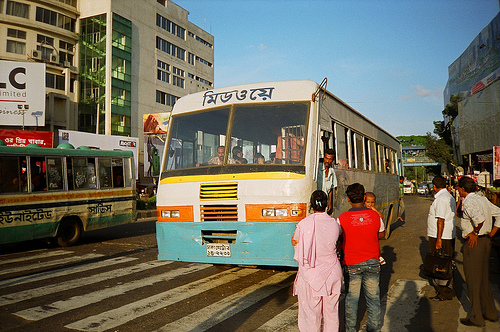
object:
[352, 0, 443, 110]
sky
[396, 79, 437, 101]
clouds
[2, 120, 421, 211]
these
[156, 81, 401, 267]
bus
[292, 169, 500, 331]
people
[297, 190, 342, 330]
woman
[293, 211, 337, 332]
pink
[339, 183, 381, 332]
man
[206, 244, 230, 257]
plate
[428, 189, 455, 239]
shirt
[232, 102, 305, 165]
window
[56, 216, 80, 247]
tire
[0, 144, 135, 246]
bus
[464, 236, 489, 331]
pants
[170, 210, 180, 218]
headlights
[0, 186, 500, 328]
street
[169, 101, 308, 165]
through windows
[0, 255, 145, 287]
line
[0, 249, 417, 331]
stripe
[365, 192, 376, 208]
child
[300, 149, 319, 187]
out bus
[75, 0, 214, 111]
building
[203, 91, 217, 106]
letters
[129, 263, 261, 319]
lines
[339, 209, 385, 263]
shirt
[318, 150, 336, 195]
driver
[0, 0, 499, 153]
background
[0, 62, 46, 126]
advertisements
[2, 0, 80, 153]
buildings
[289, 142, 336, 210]
on bus